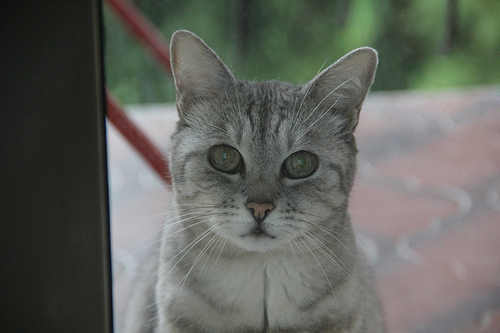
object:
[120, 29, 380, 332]
cat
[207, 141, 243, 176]
right eye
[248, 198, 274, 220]
nose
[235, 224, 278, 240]
mouth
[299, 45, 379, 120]
left ear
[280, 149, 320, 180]
eyes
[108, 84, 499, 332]
floor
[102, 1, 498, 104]
trees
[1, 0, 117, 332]
wall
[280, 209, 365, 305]
whiskers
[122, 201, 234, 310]
whiskers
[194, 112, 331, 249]
face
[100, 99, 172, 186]
rail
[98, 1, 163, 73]
rail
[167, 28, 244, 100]
ears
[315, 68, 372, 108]
inside